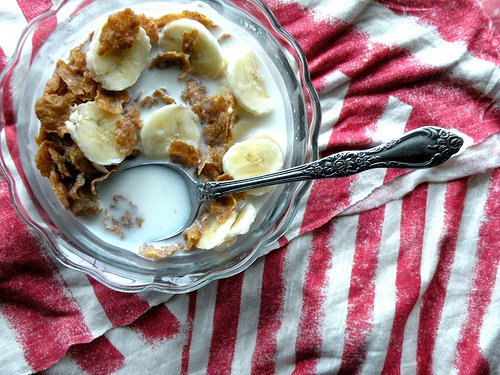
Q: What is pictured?
A: Bowl of cereal.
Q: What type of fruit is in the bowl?
A: Bananas.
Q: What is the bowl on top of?
A: A red and white cloth.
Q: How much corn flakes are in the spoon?
A: One.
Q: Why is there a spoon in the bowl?
A: To eat with.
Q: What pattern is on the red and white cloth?
A: Stripes.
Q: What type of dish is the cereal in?
A: A bowl.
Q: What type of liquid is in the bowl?
A: Milk.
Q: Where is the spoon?
A: In the bowl.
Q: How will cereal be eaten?
A: Spoon.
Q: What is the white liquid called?
A: Milk.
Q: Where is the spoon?
A: Bowl.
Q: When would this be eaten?
A: Breakfast.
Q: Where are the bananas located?
A: Top of bran.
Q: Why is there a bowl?
A: Hold cereal.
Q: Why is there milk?
A: Moisten food.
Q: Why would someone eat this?
A: Hungry.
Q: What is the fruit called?
A: Banana.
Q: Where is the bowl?
A: Cloth.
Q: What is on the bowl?
A: Cereal and banana.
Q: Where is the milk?
A: In the bowl.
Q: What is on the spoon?
A: Milk.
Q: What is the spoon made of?
A: Stainless steel.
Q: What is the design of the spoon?
A: Flowers.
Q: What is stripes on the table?
A: A tablecloth.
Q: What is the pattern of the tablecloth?
A: Striped.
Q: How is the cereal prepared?
A: Putting the ingredients together.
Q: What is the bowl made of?
A: Glass.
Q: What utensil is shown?
A: Spoon.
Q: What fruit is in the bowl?
A: Bananas.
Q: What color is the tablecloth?
A: Red, white.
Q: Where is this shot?
A: Table.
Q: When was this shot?
A: Daytime.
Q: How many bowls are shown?
A: 1.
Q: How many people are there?
A: 0.